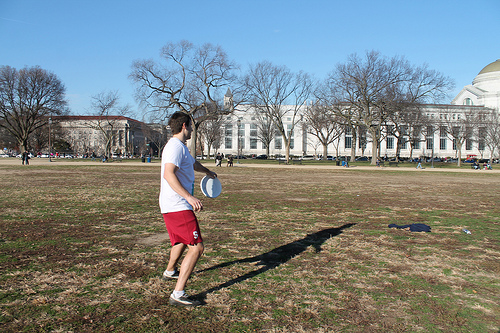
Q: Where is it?
A: This is at the park.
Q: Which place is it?
A: It is a park.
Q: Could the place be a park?
A: Yes, it is a park.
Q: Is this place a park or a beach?
A: It is a park.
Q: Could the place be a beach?
A: No, it is a park.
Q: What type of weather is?
A: It is clear.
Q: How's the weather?
A: It is clear.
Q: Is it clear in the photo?
A: Yes, it is clear.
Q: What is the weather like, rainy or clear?
A: It is clear.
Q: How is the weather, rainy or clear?
A: It is clear.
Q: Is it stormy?
A: No, it is clear.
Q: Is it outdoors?
A: Yes, it is outdoors.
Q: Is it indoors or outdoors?
A: It is outdoors.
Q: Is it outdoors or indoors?
A: It is outdoors.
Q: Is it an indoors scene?
A: No, it is outdoors.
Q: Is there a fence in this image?
A: No, there are no fences.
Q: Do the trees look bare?
A: Yes, the trees are bare.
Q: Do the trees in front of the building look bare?
A: Yes, the trees are bare.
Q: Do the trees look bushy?
A: No, the trees are bare.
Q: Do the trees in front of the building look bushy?
A: No, the trees are bare.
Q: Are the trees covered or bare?
A: The trees are bare.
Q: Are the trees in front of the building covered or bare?
A: The trees are bare.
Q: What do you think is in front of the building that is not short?
A: The trees are in front of the building.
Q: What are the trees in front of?
A: The trees are in front of the building.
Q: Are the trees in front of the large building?
A: Yes, the trees are in front of the building.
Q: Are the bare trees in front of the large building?
A: Yes, the trees are in front of the building.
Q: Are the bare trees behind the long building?
A: No, the trees are in front of the building.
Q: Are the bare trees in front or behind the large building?
A: The trees are in front of the building.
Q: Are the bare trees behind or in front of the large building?
A: The trees are in front of the building.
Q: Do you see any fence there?
A: No, there are no fences.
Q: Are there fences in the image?
A: No, there are no fences.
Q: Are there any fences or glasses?
A: No, there are no fences or glasses.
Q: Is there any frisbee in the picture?
A: Yes, there is a frisbee.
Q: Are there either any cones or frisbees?
A: Yes, there is a frisbee.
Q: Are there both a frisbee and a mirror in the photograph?
A: No, there is a frisbee but no mirrors.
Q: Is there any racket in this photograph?
A: No, there are no rackets.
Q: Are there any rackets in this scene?
A: No, there are no rackets.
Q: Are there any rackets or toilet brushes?
A: No, there are no rackets or toilet brushes.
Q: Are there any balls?
A: No, there are no balls.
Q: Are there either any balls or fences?
A: No, there are no balls or fences.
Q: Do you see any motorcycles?
A: No, there are no motorcycles.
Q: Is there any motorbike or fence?
A: No, there are no motorcycles or fences.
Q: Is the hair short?
A: Yes, the hair is short.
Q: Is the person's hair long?
A: No, the hair is short.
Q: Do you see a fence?
A: No, there are no fences.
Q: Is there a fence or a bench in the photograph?
A: No, there are no fences or benches.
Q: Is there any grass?
A: Yes, there is grass.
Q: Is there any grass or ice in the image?
A: Yes, there is grass.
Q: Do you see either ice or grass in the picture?
A: Yes, there is grass.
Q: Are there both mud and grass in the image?
A: No, there is grass but no mud.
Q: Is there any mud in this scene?
A: No, there is no mud.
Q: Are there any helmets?
A: No, there are no helmets.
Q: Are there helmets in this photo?
A: No, there are no helmets.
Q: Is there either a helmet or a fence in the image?
A: No, there are no helmets or fences.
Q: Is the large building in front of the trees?
A: No, the building is behind the trees.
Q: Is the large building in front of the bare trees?
A: No, the building is behind the trees.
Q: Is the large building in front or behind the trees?
A: The building is behind the trees.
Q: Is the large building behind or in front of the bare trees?
A: The building is behind the trees.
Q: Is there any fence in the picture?
A: No, there are no fences.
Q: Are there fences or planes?
A: No, there are no fences or planes.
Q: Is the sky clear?
A: Yes, the sky is clear.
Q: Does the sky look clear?
A: Yes, the sky is clear.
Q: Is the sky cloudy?
A: No, the sky is clear.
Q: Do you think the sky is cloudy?
A: No, the sky is clear.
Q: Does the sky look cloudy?
A: No, the sky is clear.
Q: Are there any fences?
A: No, there are no fences.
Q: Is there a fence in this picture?
A: No, there are no fences.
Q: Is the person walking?
A: Yes, the person is walking.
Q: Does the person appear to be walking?
A: Yes, the person is walking.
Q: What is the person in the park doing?
A: The person is walking.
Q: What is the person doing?
A: The person is walking.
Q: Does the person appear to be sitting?
A: No, the person is walking.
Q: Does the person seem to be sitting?
A: No, the person is walking.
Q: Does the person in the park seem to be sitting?
A: No, the person is walking.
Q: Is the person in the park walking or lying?
A: The person is walking.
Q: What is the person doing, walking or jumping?
A: The person is walking.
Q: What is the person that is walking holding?
A: The person is holding the frisbee.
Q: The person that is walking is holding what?
A: The person is holding the frisbee.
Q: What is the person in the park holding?
A: The person is holding the frisbee.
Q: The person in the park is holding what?
A: The person is holding the frisbee.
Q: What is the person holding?
A: The person is holding the frisbee.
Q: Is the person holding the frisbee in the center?
A: Yes, the person is holding the frisbee.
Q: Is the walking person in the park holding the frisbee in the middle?
A: Yes, the person is holding the frisbee.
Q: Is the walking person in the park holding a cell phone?
A: No, the person is holding the frisbee.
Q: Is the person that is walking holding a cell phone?
A: No, the person is holding the frisbee.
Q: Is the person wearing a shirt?
A: Yes, the person is wearing a shirt.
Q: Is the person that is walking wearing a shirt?
A: Yes, the person is wearing a shirt.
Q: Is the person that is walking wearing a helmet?
A: No, the person is wearing a shirt.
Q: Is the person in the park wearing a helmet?
A: No, the person is wearing a shirt.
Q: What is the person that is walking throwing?
A: The person is throwing the frisbee.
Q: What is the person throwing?
A: The person is throwing the frisbee.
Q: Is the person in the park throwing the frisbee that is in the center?
A: Yes, the person is throwing the frisbee.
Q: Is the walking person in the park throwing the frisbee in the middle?
A: Yes, the person is throwing the frisbee.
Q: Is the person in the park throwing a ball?
A: No, the person is throwing the frisbee.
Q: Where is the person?
A: The person is in the park.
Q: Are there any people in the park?
A: Yes, there is a person in the park.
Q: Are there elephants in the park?
A: No, there is a person in the park.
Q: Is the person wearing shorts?
A: Yes, the person is wearing shorts.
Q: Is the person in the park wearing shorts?
A: Yes, the person is wearing shorts.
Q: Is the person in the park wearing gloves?
A: No, the person is wearing shorts.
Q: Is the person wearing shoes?
A: Yes, the person is wearing shoes.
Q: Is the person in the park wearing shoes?
A: Yes, the person is wearing shoes.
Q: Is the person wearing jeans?
A: No, the person is wearing shoes.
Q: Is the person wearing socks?
A: Yes, the person is wearing socks.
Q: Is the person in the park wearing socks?
A: Yes, the person is wearing socks.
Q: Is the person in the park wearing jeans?
A: No, the person is wearing socks.